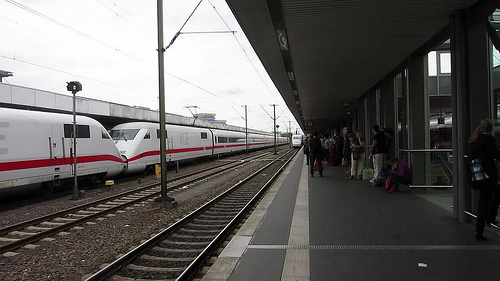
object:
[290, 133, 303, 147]
train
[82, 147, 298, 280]
tracks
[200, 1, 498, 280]
train station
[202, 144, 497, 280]
boarding platform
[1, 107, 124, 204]
train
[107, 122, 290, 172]
train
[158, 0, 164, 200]
pole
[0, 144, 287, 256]
tracks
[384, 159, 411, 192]
person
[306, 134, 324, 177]
person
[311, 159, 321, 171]
bag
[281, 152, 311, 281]
stripe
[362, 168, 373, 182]
travel bag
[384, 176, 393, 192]
travel bag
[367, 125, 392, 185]
passenger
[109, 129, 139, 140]
windshield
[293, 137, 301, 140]
windshield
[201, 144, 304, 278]
stripe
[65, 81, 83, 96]
train signal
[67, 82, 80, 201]
post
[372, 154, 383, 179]
pants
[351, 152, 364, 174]
pants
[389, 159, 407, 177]
shirt